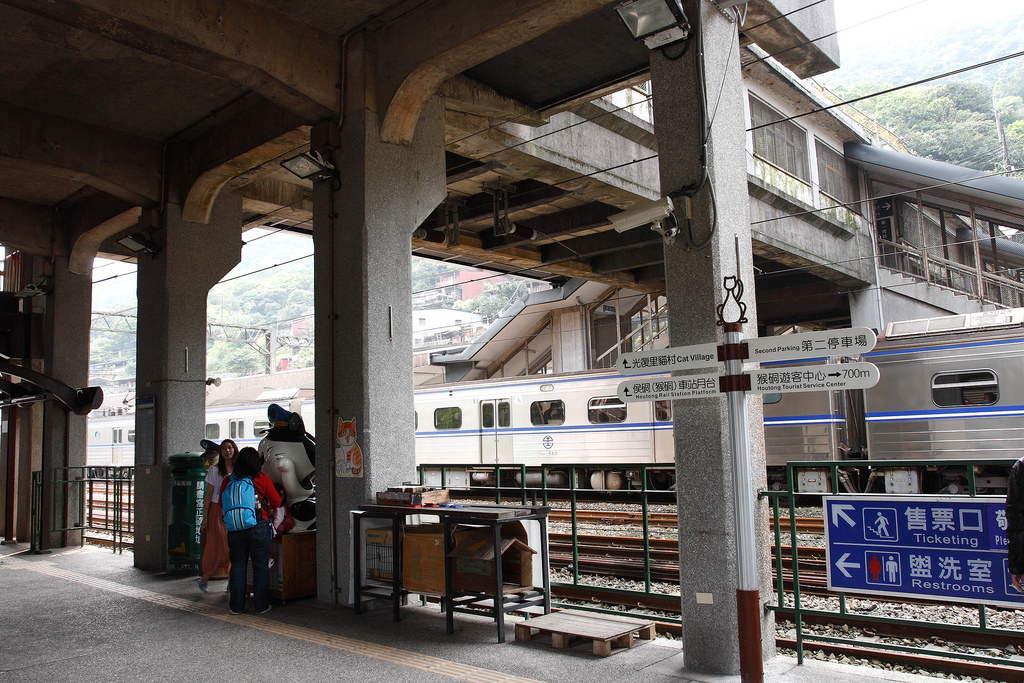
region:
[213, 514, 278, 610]
Person wearing pants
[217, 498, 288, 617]
Person is wearing pants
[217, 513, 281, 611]
Person wearing blue pants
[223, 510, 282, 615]
Person is wearing jeans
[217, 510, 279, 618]
Person wearing blue jeans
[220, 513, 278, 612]
Person is wearing blue jeans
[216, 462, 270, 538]
Person wearing a backpack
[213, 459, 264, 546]
Person is wearing a backpack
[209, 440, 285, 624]
Young girl wearing light blue backpack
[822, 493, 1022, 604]
Blue sign directing to ticketing window and restrooms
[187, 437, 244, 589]
Young girl in red dress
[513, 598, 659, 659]
Wooden shipping pallette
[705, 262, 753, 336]
Metal sign that looks like a cat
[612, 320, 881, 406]
Signs written in an Asian language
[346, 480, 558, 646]
Table with a bottom shelf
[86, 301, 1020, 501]
Silver train with blue and white stripe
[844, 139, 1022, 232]
Covered walkway over stairway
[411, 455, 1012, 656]
Green metal railing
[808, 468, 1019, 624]
sign on a fence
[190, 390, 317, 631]
people on a train platform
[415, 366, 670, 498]
car of a silver train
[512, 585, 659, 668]
wooden palette on a platform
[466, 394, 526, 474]
door of a train car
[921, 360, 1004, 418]
window on a train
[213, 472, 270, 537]
blue backpack on a passenger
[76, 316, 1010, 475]
a silver train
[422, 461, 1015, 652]
a green gate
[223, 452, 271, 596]
a person with a blue backpack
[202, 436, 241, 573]
a person in a white shirt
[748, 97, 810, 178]
a window on the building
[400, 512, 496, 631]
a trash can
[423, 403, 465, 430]
A window on a vehicle.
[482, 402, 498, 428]
A window on a vehicle.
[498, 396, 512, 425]
A window on a vehicle.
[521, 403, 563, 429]
A window on a vehicle.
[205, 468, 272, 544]
the back pack is blue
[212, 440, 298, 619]
a child carring a backpack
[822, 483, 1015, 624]
a blue sign on rail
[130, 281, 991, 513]
a silver train on tracks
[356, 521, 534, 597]
cardboard boxes under table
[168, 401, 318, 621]
people waiting on train